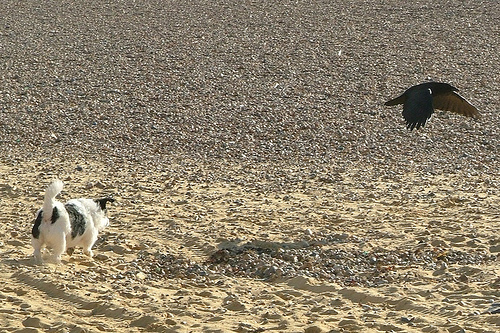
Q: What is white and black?
A: Dog.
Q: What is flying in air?
A: Bird.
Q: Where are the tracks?
A: In sand.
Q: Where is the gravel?
A: In field.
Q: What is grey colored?
A: Gravel.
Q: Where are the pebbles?
A: On ground.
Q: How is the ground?
A: Sandy.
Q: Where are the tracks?
A: In the sand.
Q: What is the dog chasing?
A: A flying bird.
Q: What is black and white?
A: The dog.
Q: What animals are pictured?
A: A dog and a bird.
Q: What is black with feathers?
A: The bird.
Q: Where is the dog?
A: In the sand.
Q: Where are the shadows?
A: On the ground.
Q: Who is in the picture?
A: A bird and a dog.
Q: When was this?
A: Daytime.